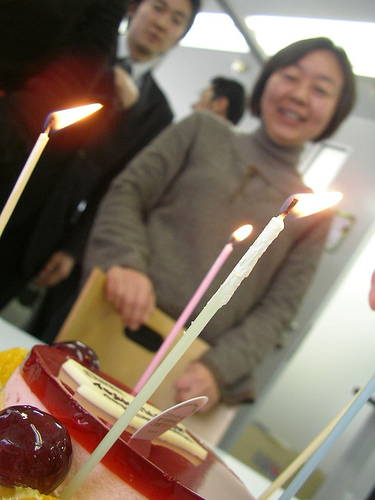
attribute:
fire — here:
[47, 106, 135, 129]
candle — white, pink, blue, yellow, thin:
[206, 245, 286, 358]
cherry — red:
[6, 410, 67, 475]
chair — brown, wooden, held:
[77, 298, 172, 386]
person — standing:
[156, 34, 315, 307]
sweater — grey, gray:
[167, 125, 264, 299]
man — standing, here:
[123, 17, 162, 148]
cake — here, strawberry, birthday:
[19, 374, 219, 500]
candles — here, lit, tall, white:
[227, 178, 349, 250]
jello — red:
[32, 363, 131, 432]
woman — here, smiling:
[134, 37, 333, 262]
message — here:
[91, 359, 177, 440]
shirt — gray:
[178, 135, 282, 259]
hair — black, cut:
[251, 41, 361, 111]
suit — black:
[87, 62, 166, 164]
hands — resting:
[109, 270, 249, 423]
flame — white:
[39, 98, 132, 153]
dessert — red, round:
[25, 328, 159, 492]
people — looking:
[69, 24, 342, 234]